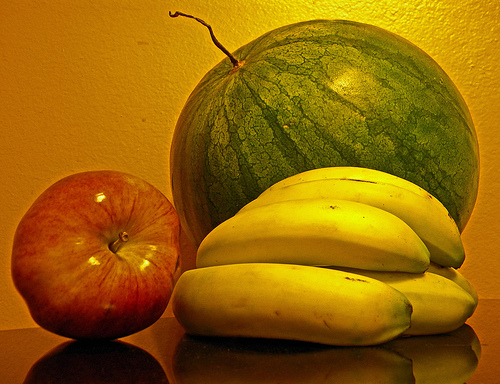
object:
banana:
[171, 262, 413, 345]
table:
[1, 299, 500, 384]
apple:
[10, 169, 181, 339]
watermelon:
[167, 10, 482, 236]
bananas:
[171, 166, 478, 345]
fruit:
[9, 19, 482, 347]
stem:
[109, 231, 129, 253]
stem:
[168, 10, 247, 74]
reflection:
[24, 339, 172, 384]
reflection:
[173, 324, 483, 383]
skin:
[299, 285, 387, 316]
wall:
[0, 0, 500, 331]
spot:
[345, 277, 370, 284]